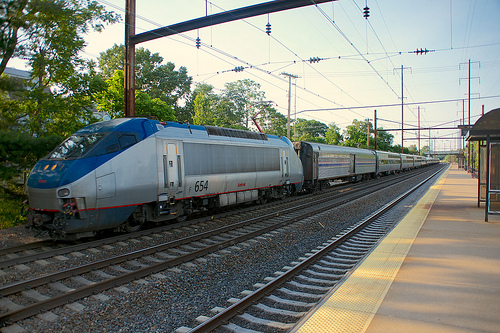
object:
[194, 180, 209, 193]
numbers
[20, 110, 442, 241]
train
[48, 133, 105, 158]
windshield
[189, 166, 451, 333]
tracks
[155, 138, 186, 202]
door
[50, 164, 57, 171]
lights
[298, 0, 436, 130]
wires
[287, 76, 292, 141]
pole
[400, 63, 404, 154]
pole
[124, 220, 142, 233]
wheels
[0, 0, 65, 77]
trees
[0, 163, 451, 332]
gravel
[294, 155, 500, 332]
platform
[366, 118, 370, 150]
pole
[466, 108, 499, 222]
shelter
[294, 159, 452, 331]
tile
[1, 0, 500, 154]
sky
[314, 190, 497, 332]
shadow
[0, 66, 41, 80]
roof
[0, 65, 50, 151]
building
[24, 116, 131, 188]
slope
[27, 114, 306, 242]
car